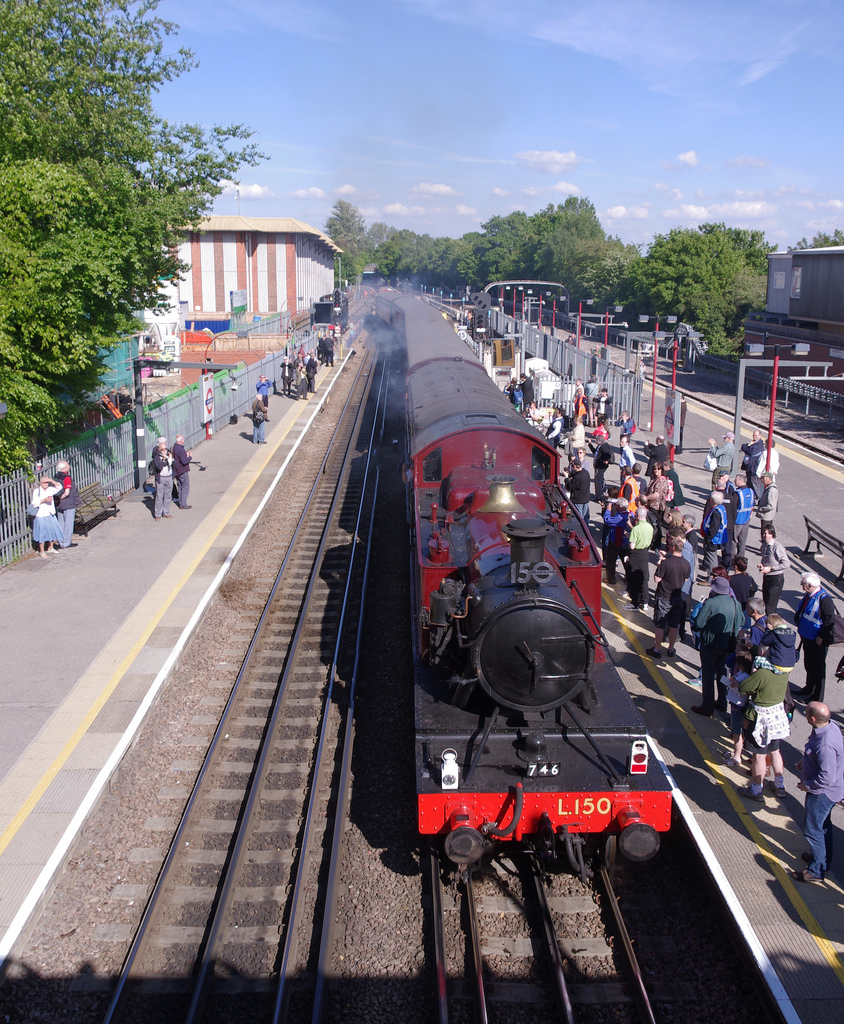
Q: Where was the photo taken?
A: At a train stop.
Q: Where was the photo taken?
A: Train stop.